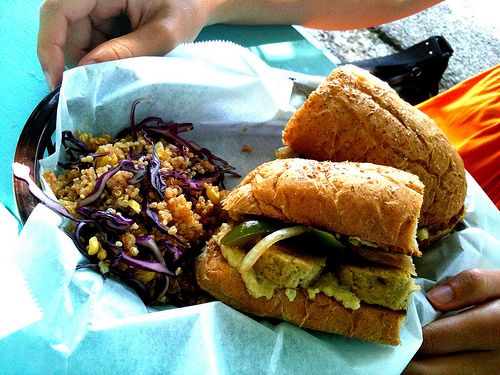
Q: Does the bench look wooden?
A: Yes, the bench is wooden.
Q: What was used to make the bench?
A: The bench is made of wood.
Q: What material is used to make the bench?
A: The bench is made of wood.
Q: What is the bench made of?
A: The bench is made of wood.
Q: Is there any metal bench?
A: No, there is a bench but it is made of wood.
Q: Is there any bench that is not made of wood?
A: No, there is a bench but it is made of wood.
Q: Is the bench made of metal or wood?
A: The bench is made of wood.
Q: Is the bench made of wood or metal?
A: The bench is made of wood.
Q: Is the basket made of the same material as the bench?
A: No, the basket is made of plastic and the bench is made of wood.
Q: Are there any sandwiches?
A: Yes, there is a sandwich.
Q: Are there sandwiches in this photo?
A: Yes, there is a sandwich.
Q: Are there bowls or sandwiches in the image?
A: Yes, there is a sandwich.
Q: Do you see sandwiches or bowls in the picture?
A: Yes, there is a sandwich.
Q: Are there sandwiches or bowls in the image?
A: Yes, there is a sandwich.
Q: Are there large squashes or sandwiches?
A: Yes, there is a large sandwich.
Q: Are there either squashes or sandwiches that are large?
A: Yes, the sandwich is large.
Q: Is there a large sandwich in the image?
A: Yes, there is a large sandwich.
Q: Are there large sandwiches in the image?
A: Yes, there is a large sandwich.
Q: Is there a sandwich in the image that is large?
A: Yes, there is a large sandwich.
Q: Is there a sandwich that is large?
A: Yes, there is a sandwich that is large.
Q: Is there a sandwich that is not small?
A: Yes, there is a large sandwich.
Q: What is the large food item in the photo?
A: The food item is a sandwich.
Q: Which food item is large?
A: The food item is a sandwich.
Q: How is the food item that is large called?
A: The food item is a sandwich.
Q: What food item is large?
A: The food item is a sandwich.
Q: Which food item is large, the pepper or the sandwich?
A: The sandwich is large.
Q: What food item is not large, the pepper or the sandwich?
A: The pepper is not large.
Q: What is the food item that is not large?
A: The food item is a pepper.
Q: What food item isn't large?
A: The food item is a pepper.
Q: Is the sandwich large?
A: Yes, the sandwich is large.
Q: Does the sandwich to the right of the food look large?
A: Yes, the sandwich is large.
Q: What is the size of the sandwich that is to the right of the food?
A: The sandwich is large.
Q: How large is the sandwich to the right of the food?
A: The sandwich is large.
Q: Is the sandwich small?
A: No, the sandwich is large.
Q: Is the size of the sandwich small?
A: No, the sandwich is large.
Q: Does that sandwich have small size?
A: No, the sandwich is large.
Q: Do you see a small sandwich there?
A: No, there is a sandwich but it is large.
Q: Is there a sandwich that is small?
A: No, there is a sandwich but it is large.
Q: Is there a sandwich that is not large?
A: No, there is a sandwich but it is large.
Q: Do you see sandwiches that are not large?
A: No, there is a sandwich but it is large.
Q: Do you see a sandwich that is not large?
A: No, there is a sandwich but it is large.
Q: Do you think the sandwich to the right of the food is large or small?
A: The sandwich is large.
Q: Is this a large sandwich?
A: Yes, this is a large sandwich.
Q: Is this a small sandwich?
A: No, this is a large sandwich.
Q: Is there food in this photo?
A: Yes, there is food.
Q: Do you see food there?
A: Yes, there is food.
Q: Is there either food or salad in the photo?
A: Yes, there is food.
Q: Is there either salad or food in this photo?
A: Yes, there is food.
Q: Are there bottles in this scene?
A: No, there are no bottles.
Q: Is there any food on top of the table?
A: Yes, there is food on top of the table.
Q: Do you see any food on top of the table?
A: Yes, there is food on top of the table.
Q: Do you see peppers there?
A: Yes, there is a pepper.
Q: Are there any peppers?
A: Yes, there is a pepper.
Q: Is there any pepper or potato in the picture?
A: Yes, there is a pepper.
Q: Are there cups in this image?
A: No, there are no cups.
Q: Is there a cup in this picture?
A: No, there are no cups.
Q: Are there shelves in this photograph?
A: No, there are no shelves.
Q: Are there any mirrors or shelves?
A: No, there are no shelves or mirrors.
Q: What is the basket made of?
A: The basket is made of plastic.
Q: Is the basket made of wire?
A: No, the basket is made of plastic.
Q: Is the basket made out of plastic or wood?
A: The basket is made of plastic.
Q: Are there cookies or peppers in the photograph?
A: Yes, there is a pepper.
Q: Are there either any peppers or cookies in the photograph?
A: Yes, there is a pepper.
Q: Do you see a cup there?
A: No, there are no cups.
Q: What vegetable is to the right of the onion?
A: The vegetable is a pepper.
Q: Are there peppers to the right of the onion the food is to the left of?
A: Yes, there is a pepper to the right of the onion.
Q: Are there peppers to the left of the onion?
A: No, the pepper is to the right of the onion.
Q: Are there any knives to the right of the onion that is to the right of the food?
A: No, there is a pepper to the right of the onion.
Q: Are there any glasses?
A: No, there are no glasses.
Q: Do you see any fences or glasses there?
A: No, there are no glasses or fences.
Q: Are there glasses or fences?
A: No, there are no glasses or fences.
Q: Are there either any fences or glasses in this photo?
A: No, there are no glasses or fences.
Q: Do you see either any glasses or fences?
A: No, there are no glasses or fences.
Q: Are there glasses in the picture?
A: No, there are no glasses.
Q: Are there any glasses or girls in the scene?
A: No, there are no glasses or girls.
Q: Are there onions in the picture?
A: Yes, there is an onion.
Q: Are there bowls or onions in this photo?
A: Yes, there is an onion.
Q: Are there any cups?
A: No, there are no cups.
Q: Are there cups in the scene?
A: No, there are no cups.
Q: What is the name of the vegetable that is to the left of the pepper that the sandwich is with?
A: The vegetable is an onion.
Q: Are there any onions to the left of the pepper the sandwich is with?
A: Yes, there is an onion to the left of the pepper.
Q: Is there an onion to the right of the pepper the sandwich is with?
A: No, the onion is to the left of the pepper.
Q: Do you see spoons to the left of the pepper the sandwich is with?
A: No, there is an onion to the left of the pepper.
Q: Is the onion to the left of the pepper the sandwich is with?
A: Yes, the onion is to the left of the pepper.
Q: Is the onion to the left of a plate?
A: No, the onion is to the left of the pepper.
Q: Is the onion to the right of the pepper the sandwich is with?
A: No, the onion is to the left of the pepper.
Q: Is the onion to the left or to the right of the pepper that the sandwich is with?
A: The onion is to the left of the pepper.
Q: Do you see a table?
A: Yes, there is a table.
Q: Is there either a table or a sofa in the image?
A: Yes, there is a table.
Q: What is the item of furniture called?
A: The piece of furniture is a table.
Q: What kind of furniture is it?
A: The piece of furniture is a table.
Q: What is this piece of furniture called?
A: This is a table.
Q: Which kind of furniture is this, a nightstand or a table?
A: This is a table.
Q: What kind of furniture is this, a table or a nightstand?
A: This is a table.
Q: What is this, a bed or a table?
A: This is a table.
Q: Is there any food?
A: Yes, there is food.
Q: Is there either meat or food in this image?
A: Yes, there is food.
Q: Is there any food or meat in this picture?
A: Yes, there is food.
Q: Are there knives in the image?
A: No, there are no knives.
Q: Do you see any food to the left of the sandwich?
A: Yes, there is food to the left of the sandwich.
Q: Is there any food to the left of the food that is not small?
A: Yes, there is food to the left of the sandwich.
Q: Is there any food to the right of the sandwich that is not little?
A: No, the food is to the left of the sandwich.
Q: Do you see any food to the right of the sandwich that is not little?
A: No, the food is to the left of the sandwich.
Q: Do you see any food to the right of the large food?
A: No, the food is to the left of the sandwich.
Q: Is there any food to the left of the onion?
A: Yes, there is food to the left of the onion.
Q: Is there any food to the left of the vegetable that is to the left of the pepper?
A: Yes, there is food to the left of the onion.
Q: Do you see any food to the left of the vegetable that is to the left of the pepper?
A: Yes, there is food to the left of the onion.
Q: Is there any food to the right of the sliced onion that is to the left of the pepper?
A: No, the food is to the left of the onion.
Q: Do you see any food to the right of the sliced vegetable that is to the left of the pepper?
A: No, the food is to the left of the onion.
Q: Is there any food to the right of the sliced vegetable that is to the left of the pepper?
A: No, the food is to the left of the onion.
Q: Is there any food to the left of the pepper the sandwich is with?
A: Yes, there is food to the left of the pepper.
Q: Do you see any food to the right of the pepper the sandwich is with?
A: No, the food is to the left of the pepper.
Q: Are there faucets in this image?
A: No, there are no faucets.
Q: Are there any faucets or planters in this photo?
A: No, there are no faucets or planters.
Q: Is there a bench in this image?
A: Yes, there is a bench.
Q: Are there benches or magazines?
A: Yes, there is a bench.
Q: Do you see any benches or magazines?
A: Yes, there is a bench.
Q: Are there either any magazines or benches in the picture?
A: Yes, there is a bench.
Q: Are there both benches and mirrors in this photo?
A: No, there is a bench but no mirrors.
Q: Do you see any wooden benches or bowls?
A: Yes, there is a wood bench.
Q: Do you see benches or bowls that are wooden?
A: Yes, the bench is wooden.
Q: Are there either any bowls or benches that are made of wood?
A: Yes, the bench is made of wood.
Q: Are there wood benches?
A: Yes, there is a bench that is made of wood.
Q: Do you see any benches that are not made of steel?
A: Yes, there is a bench that is made of wood.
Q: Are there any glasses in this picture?
A: No, there are no glasses.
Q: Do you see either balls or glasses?
A: No, there are no glasses or balls.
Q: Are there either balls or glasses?
A: No, there are no glasses or balls.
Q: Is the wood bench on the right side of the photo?
A: Yes, the bench is on the right of the image.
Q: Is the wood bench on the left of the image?
A: No, the bench is on the right of the image.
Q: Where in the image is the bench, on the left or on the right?
A: The bench is on the right of the image.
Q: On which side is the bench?
A: The bench is on the right of the image.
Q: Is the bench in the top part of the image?
A: Yes, the bench is in the top of the image.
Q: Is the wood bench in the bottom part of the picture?
A: No, the bench is in the top of the image.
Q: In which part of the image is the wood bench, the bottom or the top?
A: The bench is in the top of the image.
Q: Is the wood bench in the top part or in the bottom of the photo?
A: The bench is in the top of the image.